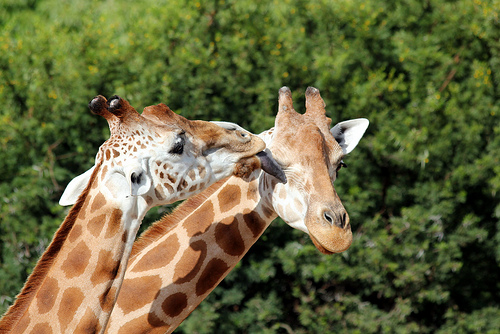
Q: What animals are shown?
A: Giraffes.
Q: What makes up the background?
A: Trees.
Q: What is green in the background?
A: Trees.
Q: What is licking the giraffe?
A: A giraffe.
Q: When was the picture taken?
A: During daylight hours.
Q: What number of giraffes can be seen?
A: Two.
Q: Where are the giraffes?
A: In front of the trees.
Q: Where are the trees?
A: Behind the giraffes.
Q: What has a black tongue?
A: The giraffe.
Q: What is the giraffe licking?
A: Another giraffe.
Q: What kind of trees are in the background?
A: Green trees.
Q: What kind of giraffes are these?
A: Mates.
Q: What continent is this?
A: Africa.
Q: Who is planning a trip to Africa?
A: Freida Jones.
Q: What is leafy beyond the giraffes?
A: Trees.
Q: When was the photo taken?
A: Day time.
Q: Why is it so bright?
A: Sunny.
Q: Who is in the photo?
A: Giraffes.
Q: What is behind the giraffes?
A: Trees.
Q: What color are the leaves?
A: Green.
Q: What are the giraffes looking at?
A: Each Other.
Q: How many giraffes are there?
A: Two.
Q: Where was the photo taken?
A: At a zoo.